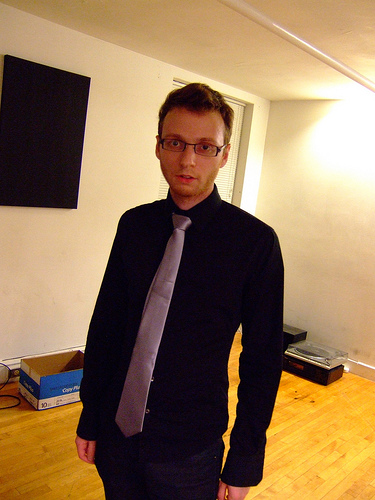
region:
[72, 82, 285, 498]
Young man wearing a purple tie.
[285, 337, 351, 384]
Record player on the floor.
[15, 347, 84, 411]
box on the floor.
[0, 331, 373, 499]
Hard wood floor covering the ground.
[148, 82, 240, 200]
Glasses on the male.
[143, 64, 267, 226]
White window in the wall.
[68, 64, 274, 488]
Black shirt on the young man.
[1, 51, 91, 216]
Television on the wall.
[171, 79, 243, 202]
White blinds on the window.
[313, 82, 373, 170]
Light in the background.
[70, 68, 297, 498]
man wearing a black shirt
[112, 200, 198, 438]
a purple tie over a black shirt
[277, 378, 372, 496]
a floor of parket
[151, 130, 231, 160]
glasses on a face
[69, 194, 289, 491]
a black long sleeve shirt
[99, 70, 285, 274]
hair of man is short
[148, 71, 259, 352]
a white door behind a man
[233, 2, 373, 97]
a tube below the celing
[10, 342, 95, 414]
an empty box on the floor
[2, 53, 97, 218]
the board is black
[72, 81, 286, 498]
Man wearing a black dress shirt and jeans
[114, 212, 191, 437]
Shiny purple necktie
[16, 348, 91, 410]
Bottom portion of a printer paper box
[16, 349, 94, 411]
Open blue cardboard box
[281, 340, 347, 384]
Small record player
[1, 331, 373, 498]
Light brown hardwood floor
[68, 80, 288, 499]
Man wearing glasses and a purple tie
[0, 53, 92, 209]
Black rectangle hanging on a wall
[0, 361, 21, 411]
Black electrical cords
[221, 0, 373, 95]
White pole going across a ceiling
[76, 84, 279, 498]
man posing for photo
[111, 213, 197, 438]
pale purple necktie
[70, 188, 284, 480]
black dress shirt man is wearing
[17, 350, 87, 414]
blue and white box without a lid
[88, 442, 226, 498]
blue jeans man is wearing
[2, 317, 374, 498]
hardwood floors in the room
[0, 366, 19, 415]
black cord on the floor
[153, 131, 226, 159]
black framed glasses of man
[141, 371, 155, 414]
two buttons on black shirt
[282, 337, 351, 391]
record player sitting on the floor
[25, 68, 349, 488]
man posing for a picture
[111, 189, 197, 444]
solid light purple tie around man's neck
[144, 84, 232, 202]
man wearing eye glasses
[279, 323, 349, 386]
old fashioned record player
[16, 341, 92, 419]
blue and white cardboard box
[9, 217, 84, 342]
walls painted solid white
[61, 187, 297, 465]
man wearing a black dress shirt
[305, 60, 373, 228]
light shining on wall and ceiling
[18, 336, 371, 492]
light colored wood floor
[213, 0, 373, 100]
white pipe along ceiling